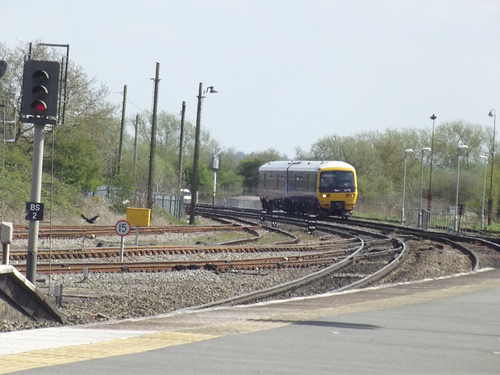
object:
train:
[257, 160, 357, 220]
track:
[328, 209, 471, 297]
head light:
[322, 193, 327, 198]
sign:
[115, 220, 132, 236]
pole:
[190, 83, 207, 222]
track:
[6, 198, 213, 261]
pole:
[179, 101, 186, 223]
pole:
[146, 63, 157, 209]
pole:
[131, 116, 145, 174]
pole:
[114, 85, 126, 181]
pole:
[399, 147, 413, 225]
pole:
[417, 148, 425, 225]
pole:
[450, 144, 464, 235]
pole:
[209, 153, 221, 209]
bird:
[80, 213, 101, 224]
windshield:
[320, 170, 350, 196]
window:
[295, 175, 301, 179]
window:
[267, 171, 275, 179]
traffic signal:
[17, 61, 60, 125]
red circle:
[33, 101, 50, 112]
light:
[203, 81, 218, 95]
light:
[404, 147, 415, 157]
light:
[419, 144, 436, 157]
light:
[456, 138, 468, 155]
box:
[126, 207, 150, 227]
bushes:
[0, 143, 99, 213]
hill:
[4, 146, 112, 221]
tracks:
[37, 214, 462, 289]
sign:
[25, 202, 44, 220]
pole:
[21, 124, 48, 283]